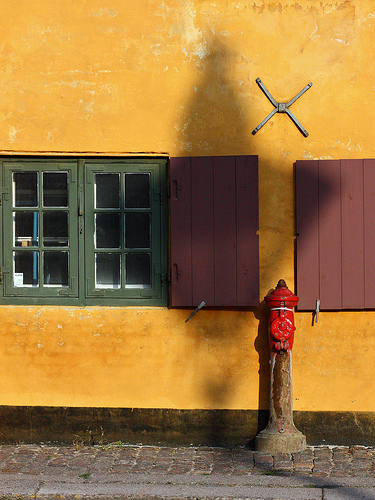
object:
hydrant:
[255, 278, 307, 452]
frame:
[1, 158, 79, 300]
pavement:
[0, 445, 373, 497]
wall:
[0, 0, 374, 408]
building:
[0, 0, 374, 445]